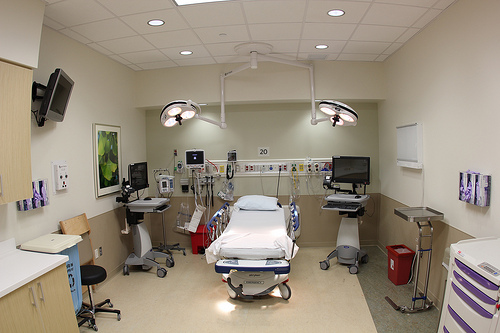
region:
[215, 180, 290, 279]
A bed in the room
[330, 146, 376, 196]
A monitor screen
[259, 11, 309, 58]
A ceiling in the room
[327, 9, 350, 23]
Lighting on the ceiling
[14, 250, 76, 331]
A cabinet near the wall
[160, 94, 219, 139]
light bulbs in the room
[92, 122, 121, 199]
Wall hanging on the wall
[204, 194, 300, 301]
the hospital bed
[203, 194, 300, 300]
the white sheets on the hospital bed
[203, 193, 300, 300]
the pillow on the hospital bed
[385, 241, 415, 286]
the narrow red trash can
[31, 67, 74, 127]
the flat panel tv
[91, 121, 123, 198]
the picture is hanging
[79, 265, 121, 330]
the rolling stool with a black seat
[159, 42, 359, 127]
the two moveable lights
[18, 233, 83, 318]
the tall light blue bin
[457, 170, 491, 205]
the cardboard glove boxes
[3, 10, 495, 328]
operating room of a hospital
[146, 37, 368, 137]
bog light lamps on the ceiling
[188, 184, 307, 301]
the bed is movible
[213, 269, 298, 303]
back wheels of a bed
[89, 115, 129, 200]
picture is on the wall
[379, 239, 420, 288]
the rash can is red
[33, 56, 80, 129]
a TV mounted on the wall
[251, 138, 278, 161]
number 20 on the wall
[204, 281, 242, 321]
light reflected on the floor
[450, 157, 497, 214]
boxes of gloves on the wall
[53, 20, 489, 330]
Empty operating room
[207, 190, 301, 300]
Patient bed in a hospital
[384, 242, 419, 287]
Garbage can for bio hazard materials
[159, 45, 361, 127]
Lights over patient bed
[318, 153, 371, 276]
Computer on rolling stand in room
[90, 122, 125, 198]
Picture on wall in hospital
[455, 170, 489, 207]
boxes of gloves on wall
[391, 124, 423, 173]
Lighted screen for viewing xrays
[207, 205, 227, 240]
Handrails on left side of patient bed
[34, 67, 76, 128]
TV mounted to wall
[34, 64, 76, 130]
Television on the wall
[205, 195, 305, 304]
Hospital bed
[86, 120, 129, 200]
Framed picture of leaves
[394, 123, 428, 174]
Light box used for viewing X-Rays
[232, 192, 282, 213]
White pillow on a hospital bed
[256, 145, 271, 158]
A placard on the wall with the number 20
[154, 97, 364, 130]
Two hanging sets of lights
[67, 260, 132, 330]
A wheeled stool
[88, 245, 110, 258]
A white and a silver electrical outlet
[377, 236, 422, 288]
A red waste basket next to a silver tray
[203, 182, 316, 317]
Bed in a hospital room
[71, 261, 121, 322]
Black stool in a hospital room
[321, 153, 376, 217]
Computer in a hospital room